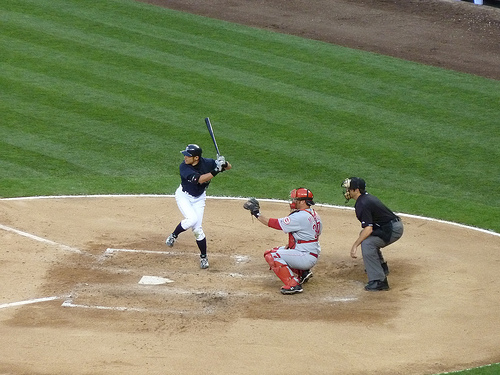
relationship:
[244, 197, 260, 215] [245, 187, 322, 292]
mitt on catcher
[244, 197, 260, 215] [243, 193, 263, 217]
mitt on hand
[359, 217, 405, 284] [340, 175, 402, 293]
pants on umpire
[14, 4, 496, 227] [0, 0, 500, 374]
grass in baseball field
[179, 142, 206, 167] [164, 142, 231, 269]
head of man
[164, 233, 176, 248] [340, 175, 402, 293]
foot of umpire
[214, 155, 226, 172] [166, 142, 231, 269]
hand of man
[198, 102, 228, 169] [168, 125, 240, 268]
bat in man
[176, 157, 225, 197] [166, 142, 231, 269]
shirt on man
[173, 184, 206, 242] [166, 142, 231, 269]
pants on man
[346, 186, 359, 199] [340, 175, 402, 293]
face on umpire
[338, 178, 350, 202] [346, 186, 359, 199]
mask on face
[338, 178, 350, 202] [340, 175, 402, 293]
mask on umpire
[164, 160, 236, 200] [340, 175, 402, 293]
shirt on umpire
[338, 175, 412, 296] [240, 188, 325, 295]
umpire behind catcher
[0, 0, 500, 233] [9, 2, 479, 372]
grass on baseball field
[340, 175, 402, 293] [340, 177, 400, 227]
umpire wearing black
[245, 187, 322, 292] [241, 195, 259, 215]
catcher has mitt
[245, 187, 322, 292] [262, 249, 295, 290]
catcher wearing shin guard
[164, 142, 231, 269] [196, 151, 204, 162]
man has an ear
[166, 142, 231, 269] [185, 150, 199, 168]
man has face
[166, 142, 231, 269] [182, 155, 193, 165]
man has nose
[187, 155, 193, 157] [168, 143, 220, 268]
eye of man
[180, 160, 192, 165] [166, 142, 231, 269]
chin of man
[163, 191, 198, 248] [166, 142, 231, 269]
leg of man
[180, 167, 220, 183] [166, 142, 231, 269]
arm of man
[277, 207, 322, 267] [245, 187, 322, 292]
gray uniform on catcher